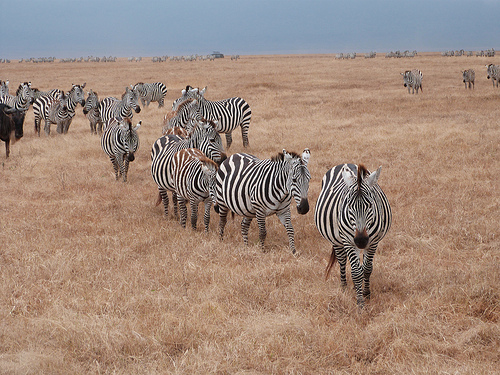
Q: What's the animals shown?
A: Zebras.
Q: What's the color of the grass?
A: Brown.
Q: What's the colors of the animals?
A: Black and white.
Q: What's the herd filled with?
A: Zebras.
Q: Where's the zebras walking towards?
A: Camera.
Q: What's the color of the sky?
A: Blue.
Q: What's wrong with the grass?
A: Dried up.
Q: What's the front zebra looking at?
A: Camera.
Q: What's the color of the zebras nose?
A: Black.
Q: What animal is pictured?
A: Zebra.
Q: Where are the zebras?
A: Field.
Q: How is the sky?
A: Blue.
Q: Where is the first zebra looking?
A: Straight.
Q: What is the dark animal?
A: Cow.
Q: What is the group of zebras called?
A: Herd.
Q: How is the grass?
A: Dry.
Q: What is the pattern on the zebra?
A: Striped.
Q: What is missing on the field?
A: Trees.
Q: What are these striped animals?
A: Zebras.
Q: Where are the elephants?
A: There are none.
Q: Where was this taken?
A: In the wild.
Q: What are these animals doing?
A: Walking.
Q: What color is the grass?
A: Brown.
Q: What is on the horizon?
A: More zebras.